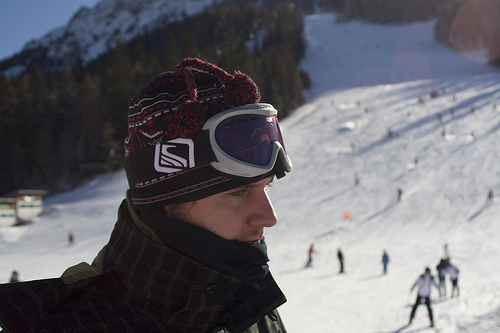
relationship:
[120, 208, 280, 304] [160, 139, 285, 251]
scarf across man's face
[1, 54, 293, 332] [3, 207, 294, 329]
man wearing jacket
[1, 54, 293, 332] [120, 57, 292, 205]
man wearing hat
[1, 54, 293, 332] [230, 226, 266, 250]
man has beard